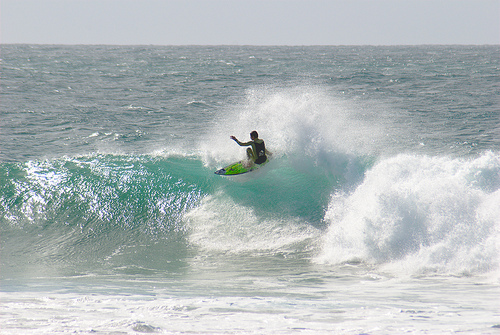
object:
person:
[228, 131, 273, 169]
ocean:
[0, 44, 498, 334]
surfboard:
[213, 157, 275, 177]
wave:
[0, 145, 498, 254]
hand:
[228, 135, 236, 140]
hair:
[248, 131, 257, 140]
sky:
[0, 0, 500, 45]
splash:
[211, 78, 381, 170]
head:
[249, 130, 258, 140]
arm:
[234, 139, 249, 146]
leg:
[244, 147, 252, 159]